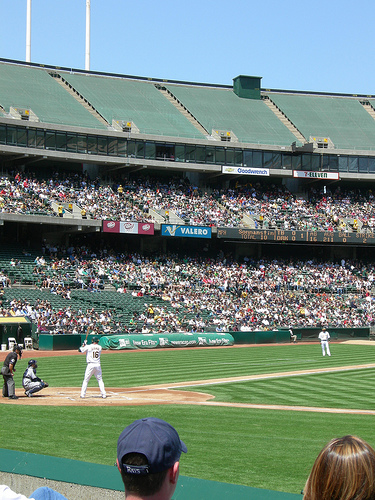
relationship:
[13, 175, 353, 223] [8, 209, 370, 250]
people are in stand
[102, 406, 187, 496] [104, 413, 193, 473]
person wearing cap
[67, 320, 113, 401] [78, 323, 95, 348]
player holding bat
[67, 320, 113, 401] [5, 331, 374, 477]
player in field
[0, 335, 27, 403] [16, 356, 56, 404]
umpire behind catcher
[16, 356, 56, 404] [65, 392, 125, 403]
catcher behind home plate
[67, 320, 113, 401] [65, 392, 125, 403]
player on side of home plate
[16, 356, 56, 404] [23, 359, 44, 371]
player wearing helmet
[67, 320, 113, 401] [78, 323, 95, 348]
player has bat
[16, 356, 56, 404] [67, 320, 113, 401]
catcher behind player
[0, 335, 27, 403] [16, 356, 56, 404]
umpire stands behind catcher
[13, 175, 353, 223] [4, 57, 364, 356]
people are in baseball stadium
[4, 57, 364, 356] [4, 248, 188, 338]
baseball stadium has seats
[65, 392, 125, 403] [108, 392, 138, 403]
home plate has markings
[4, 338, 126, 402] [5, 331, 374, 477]
players are on field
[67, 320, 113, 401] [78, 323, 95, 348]
player holds bat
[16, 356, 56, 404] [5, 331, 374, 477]
catcher on field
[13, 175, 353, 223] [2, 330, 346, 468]
people are at game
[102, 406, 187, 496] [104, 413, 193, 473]
person wears cap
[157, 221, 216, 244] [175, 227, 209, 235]
sign says valero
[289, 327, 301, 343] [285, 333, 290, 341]
man sits in chair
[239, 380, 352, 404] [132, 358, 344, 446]
pattern in grass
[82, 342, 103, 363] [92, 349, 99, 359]
jersey reads 16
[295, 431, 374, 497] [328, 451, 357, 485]
woman has hair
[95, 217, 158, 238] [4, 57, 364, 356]
dr pepper banner in baseball stadium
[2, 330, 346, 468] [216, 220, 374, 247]
game has scoreboard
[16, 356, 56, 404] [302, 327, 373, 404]
catcher in a team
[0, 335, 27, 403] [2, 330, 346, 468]
umpire in game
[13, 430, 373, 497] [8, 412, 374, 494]
spectators are in foreground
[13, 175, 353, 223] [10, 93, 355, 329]
people are in background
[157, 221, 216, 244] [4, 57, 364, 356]
sign in baseball stadium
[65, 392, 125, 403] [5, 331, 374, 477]
home plate on field